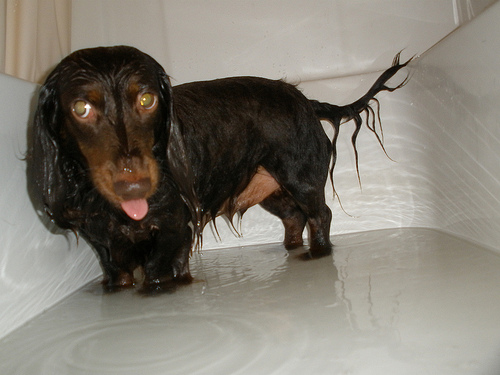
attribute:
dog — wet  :
[51, 60, 344, 229]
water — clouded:
[168, 251, 395, 363]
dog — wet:
[6, 3, 498, 373]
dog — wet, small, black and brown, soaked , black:
[23, 41, 413, 293]